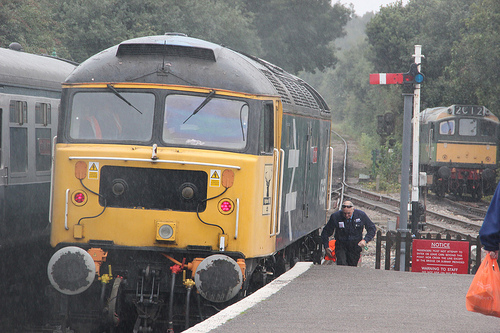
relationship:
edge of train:
[51, 145, 98, 247] [45, 30, 332, 308]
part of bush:
[443, 58, 474, 89] [442, 25, 480, 77]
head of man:
[338, 198, 356, 215] [322, 195, 377, 271]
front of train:
[39, 25, 289, 327] [14, 10, 381, 307]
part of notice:
[441, 238, 466, 273] [404, 229, 476, 287]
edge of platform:
[179, 253, 305, 332] [183, 262, 499, 332]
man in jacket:
[321, 201, 377, 267] [321, 209, 373, 247]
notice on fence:
[411, 239, 469, 276] [364, 223, 484, 285]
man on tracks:
[317, 192, 380, 267] [333, 125, 492, 248]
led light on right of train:
[217, 197, 236, 215] [39, 30, 324, 325]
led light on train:
[208, 197, 238, 219] [81, 45, 383, 265]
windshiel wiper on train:
[183, 90, 216, 124] [50, 39, 335, 330]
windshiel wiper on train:
[106, 83, 143, 114] [50, 39, 335, 330]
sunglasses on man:
[328, 203, 366, 209] [324, 184, 362, 267]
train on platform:
[45, 30, 332, 308] [177, 256, 498, 331]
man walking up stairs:
[321, 201, 377, 267] [310, 234, 370, 272]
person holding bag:
[481, 181, 498, 244] [463, 252, 497, 321]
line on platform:
[176, 262, 314, 333] [177, 256, 498, 331]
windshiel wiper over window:
[105, 81, 140, 115] [71, 92, 152, 140]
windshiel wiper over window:
[180, 85, 216, 124] [162, 92, 246, 148]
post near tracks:
[409, 41, 424, 208] [339, 159, 413, 228]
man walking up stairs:
[321, 201, 377, 267] [319, 240, 399, 290]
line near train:
[167, 250, 342, 330] [37, 37, 357, 307]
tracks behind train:
[333, 125, 492, 248] [39, 30, 324, 325]